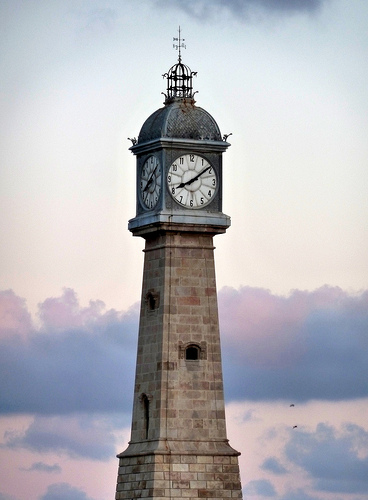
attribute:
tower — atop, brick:
[127, 66, 251, 481]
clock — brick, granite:
[160, 148, 281, 255]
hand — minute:
[175, 158, 240, 197]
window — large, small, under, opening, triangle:
[175, 338, 236, 383]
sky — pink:
[24, 224, 122, 355]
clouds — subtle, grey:
[33, 59, 135, 384]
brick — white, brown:
[141, 253, 235, 294]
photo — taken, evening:
[47, 19, 331, 491]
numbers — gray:
[126, 159, 213, 203]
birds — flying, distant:
[236, 360, 341, 480]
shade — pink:
[221, 236, 367, 331]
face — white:
[162, 154, 201, 186]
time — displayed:
[133, 151, 234, 209]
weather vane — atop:
[131, 37, 240, 120]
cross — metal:
[171, 24, 226, 60]